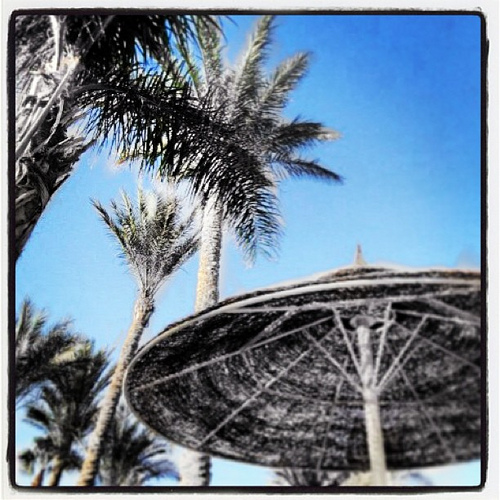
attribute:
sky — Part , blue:
[316, 25, 474, 260]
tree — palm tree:
[145, 28, 345, 308]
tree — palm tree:
[67, 188, 184, 486]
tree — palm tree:
[12, 19, 125, 229]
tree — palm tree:
[11, 314, 123, 494]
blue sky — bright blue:
[15, 14, 482, 486]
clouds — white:
[292, 187, 444, 257]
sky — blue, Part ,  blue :
[34, 13, 483, 345]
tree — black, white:
[16, 302, 90, 407]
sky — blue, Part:
[338, 70, 442, 168]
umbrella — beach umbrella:
[126, 264, 488, 465]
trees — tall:
[10, 10, 343, 486]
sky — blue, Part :
[325, 84, 440, 236]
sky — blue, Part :
[213, 458, 268, 485]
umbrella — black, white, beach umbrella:
[122, 243, 479, 484]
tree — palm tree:
[16, 13, 238, 258]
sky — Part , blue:
[343, 58, 403, 145]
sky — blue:
[359, 62, 466, 249]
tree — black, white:
[114, 86, 251, 251]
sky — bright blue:
[335, 67, 425, 164]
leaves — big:
[106, 15, 343, 255]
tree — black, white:
[128, 78, 299, 320]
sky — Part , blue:
[380, 96, 450, 191]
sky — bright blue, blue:
[13, 13, 484, 485]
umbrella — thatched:
[168, 357, 258, 428]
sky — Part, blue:
[3, 12, 470, 264]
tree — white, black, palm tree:
[8, 16, 283, 263]